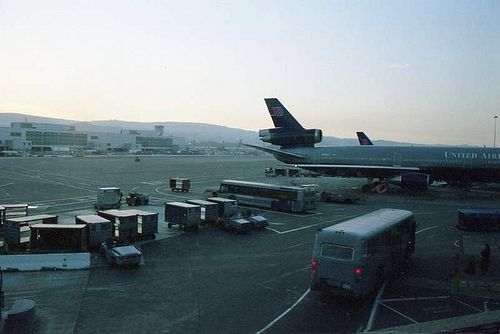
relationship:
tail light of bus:
[311, 259, 316, 266] [307, 207, 417, 300]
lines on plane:
[364, 274, 499, 331] [235, 97, 500, 195]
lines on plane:
[268, 220, 312, 237] [235, 97, 500, 195]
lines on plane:
[146, 182, 216, 199] [235, 97, 500, 195]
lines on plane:
[253, 280, 311, 332] [235, 97, 500, 195]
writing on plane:
[440, 150, 499, 161] [287, 121, 497, 198]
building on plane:
[4, 119, 92, 155] [235, 97, 500, 195]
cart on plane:
[169, 176, 189, 193] [235, 97, 500, 195]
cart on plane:
[163, 198, 202, 230] [235, 97, 500, 195]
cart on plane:
[190, 195, 217, 221] [235, 97, 500, 195]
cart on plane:
[91, 183, 124, 207] [235, 97, 500, 195]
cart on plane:
[28, 223, 89, 250] [235, 97, 500, 195]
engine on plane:
[384, 165, 446, 200] [247, 89, 499, 205]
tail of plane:
[225, 106, 292, 166] [251, 93, 499, 179]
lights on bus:
[308, 257, 368, 284] [307, 207, 417, 300]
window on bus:
[320, 240, 359, 265] [308, 229, 388, 296]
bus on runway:
[305, 202, 417, 312] [1, 156, 483, 326]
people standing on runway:
[478, 241, 492, 264] [1, 156, 483, 326]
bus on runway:
[214, 175, 319, 214] [1, 156, 483, 326]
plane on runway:
[240, 91, 498, 193] [1, 131, 498, 328]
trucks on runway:
[221, 202, 271, 234] [1, 156, 483, 326]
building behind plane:
[0, 121, 90, 155] [235, 97, 500, 195]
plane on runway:
[235, 97, 500, 195] [1, 156, 483, 326]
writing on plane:
[436, 148, 498, 168] [235, 97, 500, 195]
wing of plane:
[288, 161, 425, 177] [235, 97, 500, 195]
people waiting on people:
[480, 241, 492, 276] [464, 253, 477, 278]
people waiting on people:
[480, 241, 492, 276] [449, 250, 462, 275]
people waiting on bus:
[480, 241, 492, 276] [307, 207, 417, 300]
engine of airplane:
[382, 173, 433, 192] [258, 96, 498, 198]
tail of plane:
[256, 97, 321, 151] [235, 97, 500, 195]